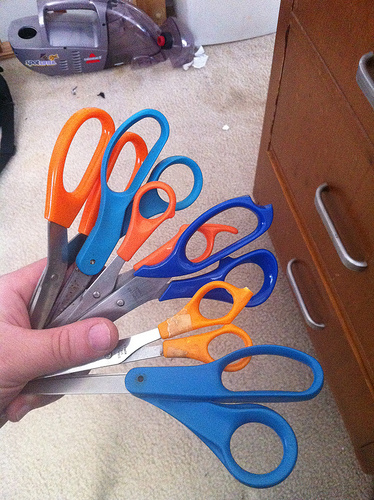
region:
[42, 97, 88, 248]
Orange handled sissors in mans hand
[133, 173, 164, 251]
Orange handled sissors in mans hand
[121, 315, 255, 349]
Orange handled sissors in mans hand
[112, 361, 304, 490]
Blue handled sissors in mans hand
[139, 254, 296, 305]
Blue handled sissors in mans hand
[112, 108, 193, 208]
Blue handled sissors in mans hand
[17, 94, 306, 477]
Several pairs of sissors in mans hand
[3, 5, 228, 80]
Small carpet shampooer on the floor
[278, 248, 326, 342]
Small silver handle on dresser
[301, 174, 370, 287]
Small silver handle on dresser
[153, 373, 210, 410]
blue scissors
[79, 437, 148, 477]
the carpet is white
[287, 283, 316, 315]
a handle on the drawer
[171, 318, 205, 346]
orange handle on the scissors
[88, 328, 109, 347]
a persons tumb nail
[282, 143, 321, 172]
a brown dresser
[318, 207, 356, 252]
the handl is silver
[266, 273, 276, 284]
reflection on the handle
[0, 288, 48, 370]
a persons hand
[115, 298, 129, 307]
a bolt in the scissors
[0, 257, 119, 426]
the hand of a person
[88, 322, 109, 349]
thumbnail is cut short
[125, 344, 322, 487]
the handle is blue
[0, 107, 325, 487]
person is holding scissors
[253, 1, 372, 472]
the drawers are brown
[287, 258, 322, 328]
the handle is metal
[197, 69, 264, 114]
stain on the carpet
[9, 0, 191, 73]
a hand held carpet cleaner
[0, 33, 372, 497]
the carpet is white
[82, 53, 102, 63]
red and white logo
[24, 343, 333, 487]
a paif of blue handled scissors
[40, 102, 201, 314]
a paif of blue handled scissors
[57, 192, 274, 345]
a paif of blue handled scissors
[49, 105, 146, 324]
a paif of orange handled scissors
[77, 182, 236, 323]
a paif of orange handled scissors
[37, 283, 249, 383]
a paif of orange handled scissors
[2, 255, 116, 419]
a hand holding scissors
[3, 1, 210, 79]
a hand held vacuum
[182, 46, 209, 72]
clutter on the floor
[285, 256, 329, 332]
a silver drawer handle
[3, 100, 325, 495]
human holding scissor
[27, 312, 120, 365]
it is thumb finger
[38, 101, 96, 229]
it is orange color scissor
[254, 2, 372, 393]
it is a drawer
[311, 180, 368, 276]
it is a drawer handle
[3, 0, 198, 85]
it is a floor cleaner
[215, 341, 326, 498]
it is scissor handle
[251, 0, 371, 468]
it is brown color cupboard